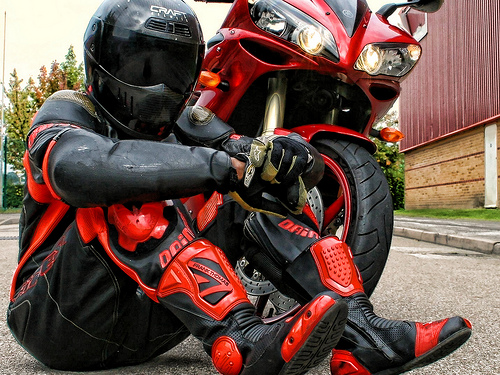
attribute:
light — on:
[293, 21, 328, 56]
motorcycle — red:
[187, 0, 445, 321]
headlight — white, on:
[248, 2, 290, 38]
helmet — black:
[82, 0, 204, 142]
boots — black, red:
[154, 239, 345, 374]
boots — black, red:
[280, 232, 472, 373]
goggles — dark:
[102, 22, 205, 95]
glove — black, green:
[247, 132, 308, 187]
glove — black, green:
[231, 153, 308, 218]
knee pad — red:
[105, 194, 172, 252]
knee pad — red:
[289, 195, 322, 231]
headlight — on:
[356, 45, 383, 74]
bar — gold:
[258, 69, 287, 136]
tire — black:
[311, 140, 394, 315]